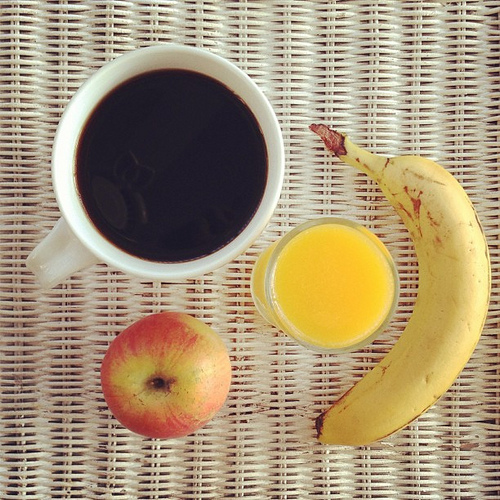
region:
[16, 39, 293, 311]
The coffee cup is full.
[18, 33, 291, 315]
The coffee cup is white.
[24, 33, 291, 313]
The coffee cup has a handle.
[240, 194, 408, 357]
The glass is full.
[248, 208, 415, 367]
The glass is clear.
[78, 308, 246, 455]
The apple is round.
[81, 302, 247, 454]
The apple is unpeeled.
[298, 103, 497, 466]
The banana is yellow.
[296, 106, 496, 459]
The banana is ripe.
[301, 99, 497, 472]
The banana is unpeeled.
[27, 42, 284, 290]
aerial view of a coffee cup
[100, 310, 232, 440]
an apple of two colors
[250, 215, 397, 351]
a glass of orange juice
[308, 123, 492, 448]
an unpeeled banana on the table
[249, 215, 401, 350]
full glass of orange juice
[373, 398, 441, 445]
a dark spot on the banana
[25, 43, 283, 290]
coffee and a ceramic cup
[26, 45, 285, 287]
a fresh cup of coffee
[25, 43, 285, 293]
a steaming cup of coffee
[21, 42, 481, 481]
Fruit and beverages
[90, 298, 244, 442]
This is an apple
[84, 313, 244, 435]
The apple is round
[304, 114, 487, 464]
This is a banana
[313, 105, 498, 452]
The banana is curved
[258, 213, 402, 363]
This is a glass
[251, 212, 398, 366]
The glass contains orange juice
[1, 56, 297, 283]
This is a coffee mug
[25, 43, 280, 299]
The mug is made of glass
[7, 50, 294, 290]
The mug contains coffee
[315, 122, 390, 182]
stem of a yellow ripe banana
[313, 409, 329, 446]
bottom tip of a ripe yellow banana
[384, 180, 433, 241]
brown spots on a whole banana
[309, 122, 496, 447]
whole yellow banana on a table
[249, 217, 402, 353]
clear glass filled with orange juice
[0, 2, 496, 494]
white wicker table with a meal on it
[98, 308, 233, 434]
red and yellow whole apple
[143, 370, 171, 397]
stem of a whole apple on a table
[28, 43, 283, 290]
white mug on a wicker table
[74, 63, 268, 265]
black coffee in a white mug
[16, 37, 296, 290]
coffee in a white cup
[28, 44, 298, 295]
cup of cofee on a white wicker table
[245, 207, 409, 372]
glass of orange juice on white wicker table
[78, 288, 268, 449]
red and yellow apple on white wicker table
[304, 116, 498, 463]
Yellow banana on white wicker table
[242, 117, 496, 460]
yellow banana next to glass of orange juice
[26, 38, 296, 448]
cup of coffee next to an apple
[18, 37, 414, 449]
cup of coffee next to orange juice and apple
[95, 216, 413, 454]
red and yellow apple next to orange juice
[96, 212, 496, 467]
glass of orange juice next to fruit